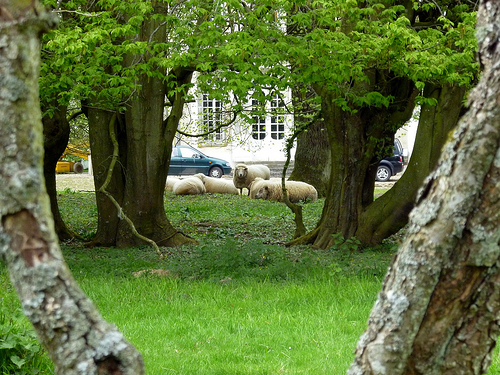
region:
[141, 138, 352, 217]
sheep on the grass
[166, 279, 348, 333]
the grass is tall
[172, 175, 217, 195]
the sheep is laying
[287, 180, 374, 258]
trunk of the tree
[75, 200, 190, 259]
the trunk is large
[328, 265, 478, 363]
trunk of the tree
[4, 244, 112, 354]
trunk of the tree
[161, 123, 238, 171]
the car is parked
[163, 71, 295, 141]
windows of the building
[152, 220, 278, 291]
the grass is shady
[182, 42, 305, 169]
a white building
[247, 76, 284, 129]
a window on the building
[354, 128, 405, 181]
the back of a black car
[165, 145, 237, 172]
a green car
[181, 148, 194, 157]
the window on the car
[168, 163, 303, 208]
sheep in the grass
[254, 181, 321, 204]
a sheep laying down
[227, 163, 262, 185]
a sheep standing up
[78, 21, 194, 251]
the trunk of a tree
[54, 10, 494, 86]
leaves on the tree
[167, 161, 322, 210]
sheep layiung in grass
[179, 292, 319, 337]
the grass is short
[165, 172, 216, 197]
the sheep is white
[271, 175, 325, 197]
the wool is white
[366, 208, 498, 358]
the trunk of the tree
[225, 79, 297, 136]
windows on the building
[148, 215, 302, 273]
shaded area of grass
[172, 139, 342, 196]
the sheep are laying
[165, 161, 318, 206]
Sheep in a city park.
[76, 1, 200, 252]
Very large tree trunk.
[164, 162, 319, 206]
Sheep with long fur coat.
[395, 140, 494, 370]
Peeled old tree on the front.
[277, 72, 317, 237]
Small skinny tree with leaves.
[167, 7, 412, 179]
Beige building in the background.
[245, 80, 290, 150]
Building with oval glass doors.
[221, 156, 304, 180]
Stairs to the building entrance.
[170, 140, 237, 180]
Green car parked in front of the building.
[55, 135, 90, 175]
Yellow construction excavator truck on the side of the building.